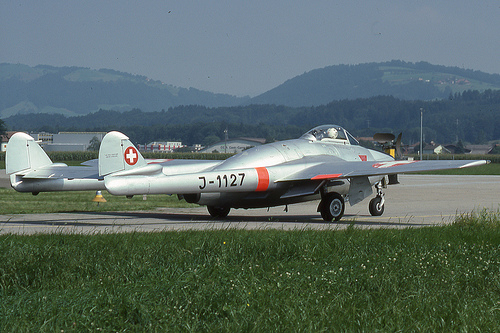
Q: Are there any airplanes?
A: Yes, there is an airplane.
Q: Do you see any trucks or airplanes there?
A: Yes, there is an airplane.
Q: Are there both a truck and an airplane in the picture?
A: No, there is an airplane but no trucks.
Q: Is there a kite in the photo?
A: No, there are no kites.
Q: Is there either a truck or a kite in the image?
A: No, there are no kites or trucks.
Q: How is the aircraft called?
A: The aircraft is an airplane.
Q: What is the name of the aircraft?
A: The aircraft is an airplane.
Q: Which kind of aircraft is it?
A: The aircraft is an airplane.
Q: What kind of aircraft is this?
A: This is an airplane.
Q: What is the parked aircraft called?
A: The aircraft is an airplane.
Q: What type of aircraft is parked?
A: The aircraft is an airplane.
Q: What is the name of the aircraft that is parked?
A: The aircraft is an airplane.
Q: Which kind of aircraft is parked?
A: The aircraft is an airplane.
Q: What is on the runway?
A: The airplane is on the runway.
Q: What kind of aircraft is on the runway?
A: The aircraft is an airplane.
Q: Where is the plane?
A: The plane is on the runway.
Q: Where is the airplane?
A: The plane is on the runway.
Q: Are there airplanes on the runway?
A: Yes, there is an airplane on the runway.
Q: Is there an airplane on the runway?
A: Yes, there is an airplane on the runway.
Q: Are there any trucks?
A: No, there are no trucks.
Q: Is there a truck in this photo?
A: No, there are no trucks.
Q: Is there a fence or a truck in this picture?
A: No, there are no trucks or fences.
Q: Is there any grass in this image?
A: Yes, there is grass.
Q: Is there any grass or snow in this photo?
A: Yes, there is grass.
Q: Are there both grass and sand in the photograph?
A: No, there is grass but no sand.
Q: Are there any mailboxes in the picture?
A: No, there are no mailboxes.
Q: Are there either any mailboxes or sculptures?
A: No, there are no mailboxes or sculptures.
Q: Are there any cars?
A: No, there are no cars.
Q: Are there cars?
A: No, there are no cars.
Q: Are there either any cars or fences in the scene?
A: No, there are no cars or fences.